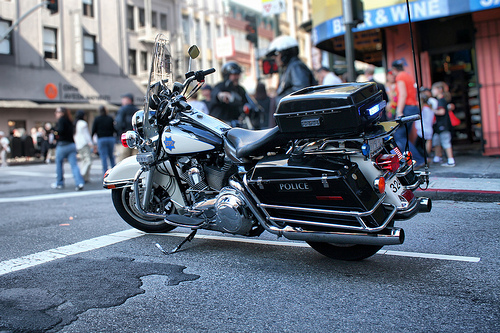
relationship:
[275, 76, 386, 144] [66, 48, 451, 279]
black box on bike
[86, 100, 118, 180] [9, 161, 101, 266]
person crossing a street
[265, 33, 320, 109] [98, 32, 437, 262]
man behind bike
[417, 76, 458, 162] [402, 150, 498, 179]
child on sidewalk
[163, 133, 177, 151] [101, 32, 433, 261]
emblem on bike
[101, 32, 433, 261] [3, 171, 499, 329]
bike on road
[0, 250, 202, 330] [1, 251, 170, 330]
dark patch on road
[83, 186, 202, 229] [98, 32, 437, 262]
front wheel of bike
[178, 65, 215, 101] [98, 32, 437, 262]
handlebar of bike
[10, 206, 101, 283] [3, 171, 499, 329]
stripe on road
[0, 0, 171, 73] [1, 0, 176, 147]
windows on building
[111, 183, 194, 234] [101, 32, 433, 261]
front wheel on bike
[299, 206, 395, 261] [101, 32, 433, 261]
motorcyle tire on bike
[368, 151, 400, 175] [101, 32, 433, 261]
light on bike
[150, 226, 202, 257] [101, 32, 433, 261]
kickstand on bike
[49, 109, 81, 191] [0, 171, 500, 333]
person crossing road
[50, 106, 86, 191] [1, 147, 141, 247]
person crossing street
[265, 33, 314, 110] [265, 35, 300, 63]
man wearing helmet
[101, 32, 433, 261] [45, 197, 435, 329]
bike on street